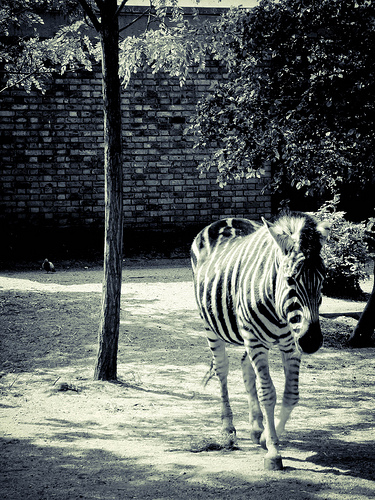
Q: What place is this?
A: It is a zoo.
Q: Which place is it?
A: It is a zoo.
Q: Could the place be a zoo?
A: Yes, it is a zoo.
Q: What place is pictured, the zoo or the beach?
A: It is the zoo.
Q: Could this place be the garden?
A: No, it is the zoo.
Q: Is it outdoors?
A: Yes, it is outdoors.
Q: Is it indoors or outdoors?
A: It is outdoors.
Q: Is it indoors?
A: No, it is outdoors.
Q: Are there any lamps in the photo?
A: No, there are no lamps.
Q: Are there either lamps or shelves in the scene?
A: No, there are no lamps or shelves.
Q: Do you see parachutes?
A: No, there are no parachutes.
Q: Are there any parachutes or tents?
A: No, there are no parachutes or tents.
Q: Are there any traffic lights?
A: No, there are no traffic lights.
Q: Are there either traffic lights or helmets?
A: No, there are no traffic lights or helmets.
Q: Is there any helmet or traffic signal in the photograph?
A: No, there are no traffic lights or helmets.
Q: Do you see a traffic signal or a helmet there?
A: No, there are no traffic lights or helmets.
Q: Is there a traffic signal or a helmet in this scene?
A: No, there are no traffic lights or helmets.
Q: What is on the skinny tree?
A: The leaves are on the tree.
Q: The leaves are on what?
A: The leaves are on the tree.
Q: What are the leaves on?
A: The leaves are on the tree.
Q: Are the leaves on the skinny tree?
A: Yes, the leaves are on the tree.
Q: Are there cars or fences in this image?
A: No, there are no fences or cars.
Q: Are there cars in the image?
A: No, there are no cars.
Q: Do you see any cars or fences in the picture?
A: No, there are no cars or fences.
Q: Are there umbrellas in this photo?
A: No, there are no umbrellas.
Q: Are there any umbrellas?
A: No, there are no umbrellas.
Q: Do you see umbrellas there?
A: No, there are no umbrellas.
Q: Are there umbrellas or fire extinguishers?
A: No, there are no umbrellas or fire extinguishers.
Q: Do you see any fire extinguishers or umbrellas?
A: No, there are no umbrellas or fire extinguishers.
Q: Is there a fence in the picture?
A: No, there are no fences.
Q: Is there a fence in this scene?
A: No, there are no fences.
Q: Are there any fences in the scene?
A: No, there are no fences.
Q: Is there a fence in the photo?
A: No, there are no fences.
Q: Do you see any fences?
A: No, there are no fences.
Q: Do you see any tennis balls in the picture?
A: No, there are no tennis balls.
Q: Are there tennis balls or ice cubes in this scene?
A: No, there are no tennis balls or ice cubes.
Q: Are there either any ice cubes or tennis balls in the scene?
A: No, there are no tennis balls or ice cubes.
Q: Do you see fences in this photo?
A: No, there are no fences.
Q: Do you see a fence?
A: No, there are no fences.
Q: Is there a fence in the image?
A: No, there are no fences.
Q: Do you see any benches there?
A: No, there are no benches.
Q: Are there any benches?
A: No, there are no benches.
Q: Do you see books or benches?
A: No, there are no benches or books.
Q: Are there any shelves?
A: No, there are no shelves.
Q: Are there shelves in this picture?
A: No, there are no shelves.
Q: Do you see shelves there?
A: No, there are no shelves.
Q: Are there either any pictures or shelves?
A: No, there are no shelves or pictures.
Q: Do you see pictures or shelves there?
A: No, there are no shelves or pictures.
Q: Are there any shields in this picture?
A: No, there are no shields.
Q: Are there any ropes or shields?
A: No, there are no shields or ropes.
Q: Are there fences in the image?
A: No, there are no fences.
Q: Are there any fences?
A: No, there are no fences.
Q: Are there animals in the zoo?
A: Yes, there is an animal in the zoo.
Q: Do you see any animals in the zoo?
A: Yes, there is an animal in the zoo.